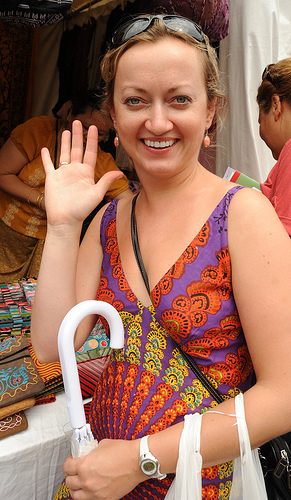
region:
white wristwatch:
[130, 444, 176, 474]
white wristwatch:
[127, 441, 155, 475]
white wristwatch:
[118, 419, 182, 495]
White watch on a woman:
[139, 433, 167, 479]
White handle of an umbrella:
[49, 299, 123, 427]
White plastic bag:
[167, 392, 267, 499]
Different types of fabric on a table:
[0, 277, 111, 442]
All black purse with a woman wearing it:
[131, 188, 289, 498]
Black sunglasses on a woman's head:
[107, 14, 209, 60]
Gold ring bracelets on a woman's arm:
[25, 185, 44, 211]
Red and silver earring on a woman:
[112, 136, 120, 146]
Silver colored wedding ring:
[57, 160, 69, 165]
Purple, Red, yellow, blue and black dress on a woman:
[54, 184, 253, 499]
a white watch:
[122, 421, 182, 492]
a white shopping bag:
[161, 402, 264, 497]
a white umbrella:
[59, 286, 117, 487]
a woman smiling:
[26, 12, 229, 182]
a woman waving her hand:
[38, 14, 263, 208]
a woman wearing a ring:
[18, 68, 235, 180]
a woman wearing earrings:
[88, 33, 257, 178]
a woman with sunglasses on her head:
[89, 6, 256, 143]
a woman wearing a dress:
[85, 15, 239, 460]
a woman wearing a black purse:
[74, 27, 288, 496]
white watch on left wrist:
[136, 434, 165, 487]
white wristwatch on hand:
[112, 419, 182, 483]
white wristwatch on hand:
[133, 419, 176, 468]